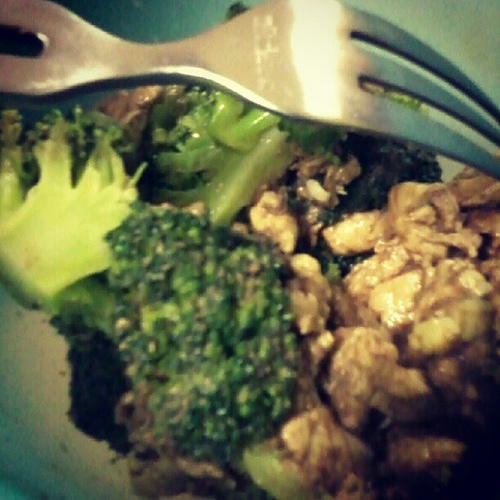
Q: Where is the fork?
A: On top of the food.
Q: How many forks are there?
A: One.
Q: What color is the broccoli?
A: Green.